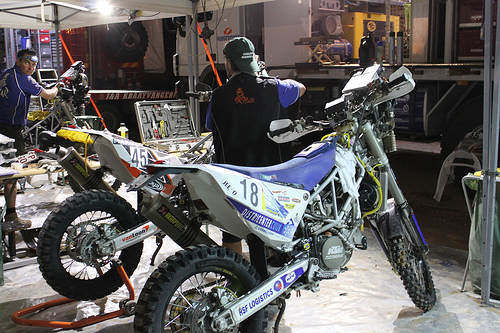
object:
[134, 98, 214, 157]
tool box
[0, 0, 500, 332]
garage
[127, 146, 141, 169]
number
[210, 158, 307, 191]
seat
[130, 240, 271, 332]
wheel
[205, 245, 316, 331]
chain case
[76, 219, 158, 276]
chain holders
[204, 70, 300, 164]
shirt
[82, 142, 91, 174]
rope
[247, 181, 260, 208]
number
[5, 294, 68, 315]
bar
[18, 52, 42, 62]
goggles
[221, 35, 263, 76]
hat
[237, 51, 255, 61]
letters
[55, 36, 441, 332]
bike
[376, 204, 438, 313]
tire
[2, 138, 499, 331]
floor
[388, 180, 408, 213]
metal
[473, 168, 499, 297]
metal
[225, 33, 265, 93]
cap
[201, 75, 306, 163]
coat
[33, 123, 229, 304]
motorcycle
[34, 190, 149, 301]
wheel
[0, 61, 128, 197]
motorcycle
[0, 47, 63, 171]
man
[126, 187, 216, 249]
muffler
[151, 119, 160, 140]
tools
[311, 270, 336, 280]
footrest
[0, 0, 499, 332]
shop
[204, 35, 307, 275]
man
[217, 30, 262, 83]
cap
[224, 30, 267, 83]
cap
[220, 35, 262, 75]
cap